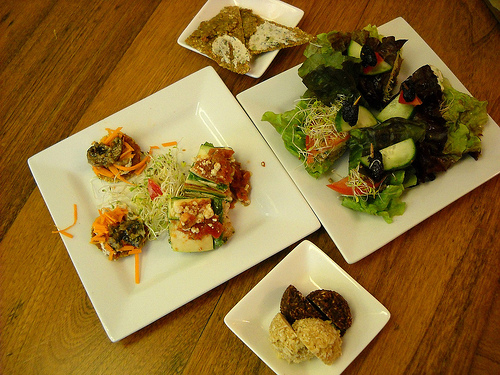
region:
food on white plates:
[2, 9, 474, 373]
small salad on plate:
[94, 138, 141, 182]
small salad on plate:
[101, 203, 143, 251]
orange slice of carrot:
[45, 199, 82, 239]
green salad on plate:
[147, 158, 174, 202]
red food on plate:
[170, 141, 244, 216]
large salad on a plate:
[278, 38, 470, 218]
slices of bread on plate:
[195, 3, 290, 78]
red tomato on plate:
[304, 121, 344, 171]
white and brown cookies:
[261, 283, 343, 371]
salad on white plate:
[276, 38, 478, 231]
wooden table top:
[59, 31, 186, 121]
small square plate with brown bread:
[246, 223, 395, 373]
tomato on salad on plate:
[316, 138, 398, 223]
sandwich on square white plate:
[155, 117, 280, 289]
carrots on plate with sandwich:
[63, 110, 180, 289]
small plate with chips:
[166, 0, 316, 80]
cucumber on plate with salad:
[346, 121, 453, 198]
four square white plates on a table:
[10, 2, 434, 373]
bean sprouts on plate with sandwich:
[120, 141, 199, 246]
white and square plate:
[35, 108, 294, 272]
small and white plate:
[229, 275, 426, 357]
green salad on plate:
[263, 85, 463, 201]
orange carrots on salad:
[78, 130, 154, 275]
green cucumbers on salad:
[344, 100, 432, 197]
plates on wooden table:
[1, 9, 495, 241]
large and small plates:
[40, 18, 495, 368]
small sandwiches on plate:
[81, 130, 253, 265]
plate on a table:
[28, 36, 363, 362]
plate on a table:
[219, 210, 405, 374]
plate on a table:
[180, 0, 307, 106]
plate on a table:
[223, 11, 495, 267]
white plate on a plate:
[220, 221, 419, 368]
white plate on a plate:
[180, 0, 291, 99]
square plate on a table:
[6, 53, 361, 350]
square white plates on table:
[4, 5, 494, 373]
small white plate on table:
[227, 236, 399, 373]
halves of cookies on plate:
[270, 279, 362, 354]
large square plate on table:
[28, 76, 283, 333]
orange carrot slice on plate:
[47, 203, 89, 241]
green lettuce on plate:
[128, 169, 175, 219]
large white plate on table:
[298, 23, 485, 243]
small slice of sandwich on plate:
[387, 68, 445, 126]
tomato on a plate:
[304, 118, 344, 155]